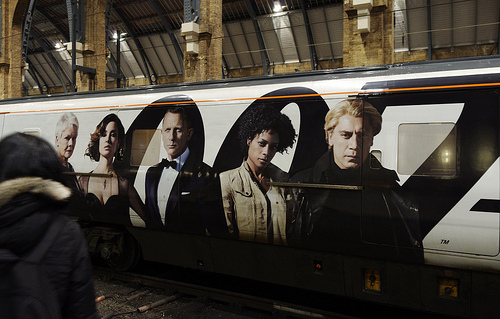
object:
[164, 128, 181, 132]
eyes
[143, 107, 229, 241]
man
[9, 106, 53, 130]
white paint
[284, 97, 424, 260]
man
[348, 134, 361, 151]
nose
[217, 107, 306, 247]
woman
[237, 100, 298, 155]
hair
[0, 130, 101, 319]
person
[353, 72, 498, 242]
ground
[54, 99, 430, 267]
people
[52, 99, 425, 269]
advertisement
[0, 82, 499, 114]
stripe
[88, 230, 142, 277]
wheel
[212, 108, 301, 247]
actor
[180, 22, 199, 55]
light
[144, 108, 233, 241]
man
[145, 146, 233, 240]
suit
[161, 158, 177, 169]
bow tie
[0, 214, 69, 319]
backpack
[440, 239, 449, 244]
trademark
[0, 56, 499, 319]
train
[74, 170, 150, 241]
dress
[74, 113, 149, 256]
woman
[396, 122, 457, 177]
window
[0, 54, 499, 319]
james bond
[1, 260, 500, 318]
tracks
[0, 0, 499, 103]
building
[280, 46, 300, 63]
window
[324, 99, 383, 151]
hair